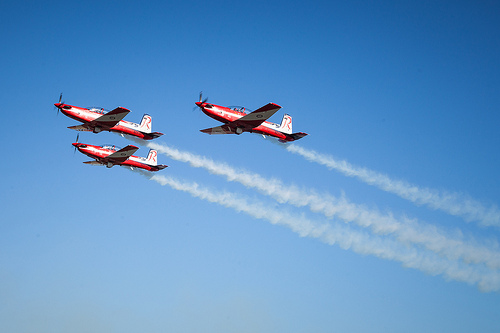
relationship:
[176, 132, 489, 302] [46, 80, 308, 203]
smoke behind planes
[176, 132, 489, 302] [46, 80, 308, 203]
smoke from planes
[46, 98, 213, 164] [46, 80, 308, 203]
propellers on planes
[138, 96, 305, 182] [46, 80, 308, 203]
tails on planes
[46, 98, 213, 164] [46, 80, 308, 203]
propellers on front of planes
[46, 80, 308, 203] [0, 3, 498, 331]
planes in sky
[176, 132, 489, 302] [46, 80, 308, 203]
smoke coming from planes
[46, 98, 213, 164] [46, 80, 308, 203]
propellers on all planes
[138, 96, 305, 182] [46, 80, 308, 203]
tails on all planes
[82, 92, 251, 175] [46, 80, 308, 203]
pilots in planes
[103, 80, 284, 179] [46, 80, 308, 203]
wings on planes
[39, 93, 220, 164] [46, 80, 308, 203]
nose on planes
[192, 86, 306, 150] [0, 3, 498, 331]
plane in sky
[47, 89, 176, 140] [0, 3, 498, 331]
plane in sky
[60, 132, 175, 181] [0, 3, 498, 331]
plane in sky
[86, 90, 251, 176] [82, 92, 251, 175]
glass over pilots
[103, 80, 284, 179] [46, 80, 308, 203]
wings on side of planes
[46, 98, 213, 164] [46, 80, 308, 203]
propellers on these planes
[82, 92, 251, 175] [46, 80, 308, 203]
pilots inside planes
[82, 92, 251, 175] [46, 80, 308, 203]
pilots inside of planes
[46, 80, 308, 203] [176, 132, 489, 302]
planes have smoke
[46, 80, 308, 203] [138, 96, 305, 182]
planes have tails